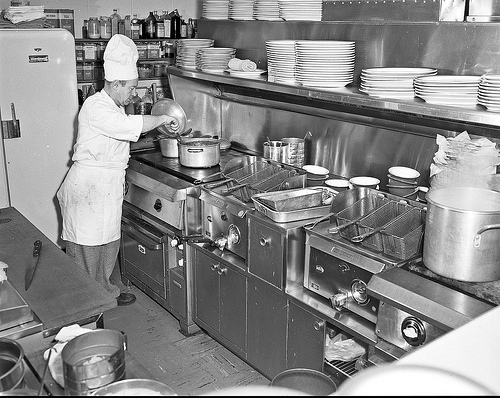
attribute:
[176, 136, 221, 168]
pot — silver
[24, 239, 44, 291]
knife — black, silver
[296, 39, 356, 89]
plates — stacked, white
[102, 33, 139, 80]
hat — white, folded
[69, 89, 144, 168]
shirt — white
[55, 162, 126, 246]
apron — white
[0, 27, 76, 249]
fridge — white